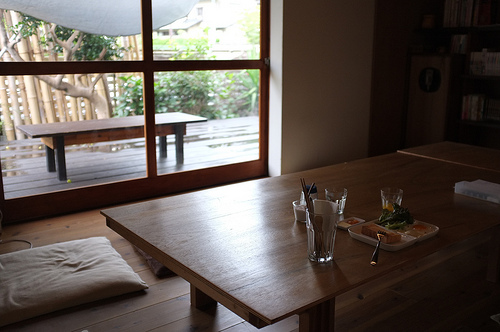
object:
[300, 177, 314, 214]
utensils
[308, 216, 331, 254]
glass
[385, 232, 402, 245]
food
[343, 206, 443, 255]
tray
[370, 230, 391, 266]
fork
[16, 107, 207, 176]
bench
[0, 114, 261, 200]
porch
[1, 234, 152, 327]
pillow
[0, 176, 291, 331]
floor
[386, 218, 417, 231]
vegetables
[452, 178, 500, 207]
napkins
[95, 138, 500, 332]
table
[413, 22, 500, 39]
shelves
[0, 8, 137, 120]
tree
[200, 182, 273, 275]
light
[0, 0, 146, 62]
window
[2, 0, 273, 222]
frame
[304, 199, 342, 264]
cup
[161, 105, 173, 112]
leaves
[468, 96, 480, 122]
books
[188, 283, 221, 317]
legs